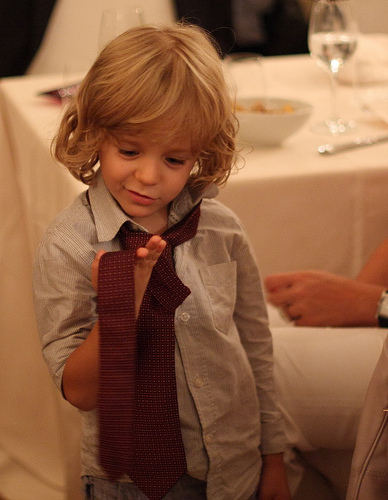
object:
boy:
[32, 21, 294, 499]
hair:
[50, 26, 242, 189]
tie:
[97, 208, 198, 498]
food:
[233, 98, 295, 114]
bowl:
[233, 91, 310, 150]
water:
[306, 33, 356, 71]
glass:
[307, 0, 357, 135]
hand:
[265, 269, 386, 327]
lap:
[271, 321, 386, 403]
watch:
[373, 288, 387, 330]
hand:
[88, 234, 167, 318]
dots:
[93, 206, 200, 496]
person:
[262, 237, 387, 496]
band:
[374, 310, 387, 333]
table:
[0, 54, 387, 499]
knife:
[316, 134, 388, 156]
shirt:
[35, 175, 285, 500]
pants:
[269, 318, 383, 491]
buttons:
[175, 310, 214, 446]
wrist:
[372, 287, 388, 326]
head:
[89, 25, 230, 219]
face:
[106, 105, 200, 218]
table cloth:
[5, 32, 386, 498]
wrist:
[265, 452, 287, 472]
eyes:
[117, 149, 187, 170]